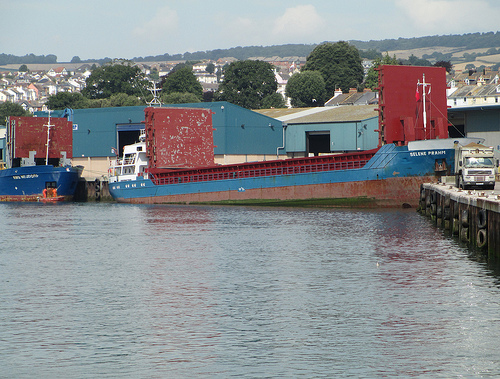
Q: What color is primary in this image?
A: Blue.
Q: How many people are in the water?
A: None.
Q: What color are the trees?
A: Green.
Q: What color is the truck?
A: White.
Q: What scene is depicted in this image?
A: A dock.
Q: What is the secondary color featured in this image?
A: Red.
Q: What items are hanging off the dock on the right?
A: Tires.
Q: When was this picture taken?
A: Daytime.